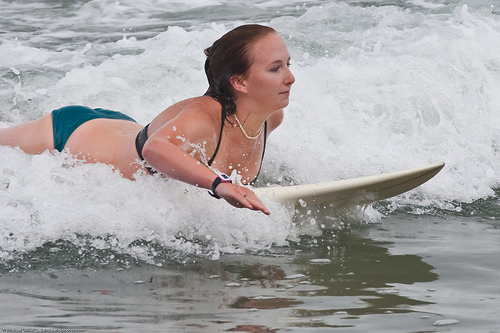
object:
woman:
[2, 24, 294, 215]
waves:
[4, 3, 493, 256]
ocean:
[3, 4, 498, 332]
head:
[205, 25, 295, 108]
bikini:
[51, 105, 269, 193]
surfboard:
[240, 161, 445, 213]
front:
[405, 160, 447, 189]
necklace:
[231, 105, 270, 144]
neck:
[234, 98, 273, 135]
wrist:
[205, 173, 230, 198]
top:
[134, 96, 274, 192]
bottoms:
[36, 104, 125, 157]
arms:
[140, 117, 270, 215]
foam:
[0, 1, 499, 262]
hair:
[193, 23, 266, 115]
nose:
[282, 66, 299, 88]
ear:
[226, 76, 246, 93]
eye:
[264, 66, 282, 75]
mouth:
[278, 90, 296, 97]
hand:
[211, 180, 269, 215]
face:
[250, 33, 295, 109]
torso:
[68, 114, 154, 181]